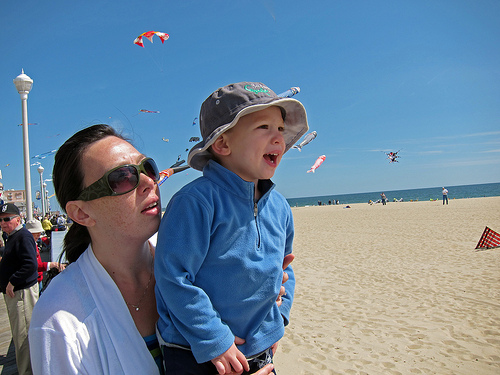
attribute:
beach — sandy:
[351, 278, 373, 296]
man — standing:
[440, 185, 459, 204]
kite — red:
[130, 25, 174, 65]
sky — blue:
[269, 15, 326, 45]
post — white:
[21, 81, 47, 211]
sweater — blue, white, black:
[195, 209, 232, 229]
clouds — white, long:
[436, 132, 488, 165]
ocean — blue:
[409, 192, 421, 201]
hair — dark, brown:
[84, 132, 87, 133]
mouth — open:
[253, 152, 286, 166]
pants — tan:
[17, 307, 34, 311]